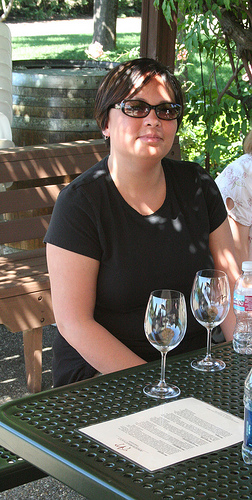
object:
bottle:
[232, 260, 252, 355]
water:
[232, 275, 252, 357]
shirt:
[42, 151, 231, 394]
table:
[0, 333, 251, 497]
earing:
[103, 136, 109, 142]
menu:
[78, 393, 244, 477]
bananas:
[91, 47, 192, 173]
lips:
[136, 133, 162, 149]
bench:
[0, 133, 180, 394]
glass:
[142, 288, 188, 401]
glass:
[189, 269, 230, 372]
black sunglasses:
[111, 98, 182, 120]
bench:
[1, 443, 49, 495]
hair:
[93, 57, 184, 148]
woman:
[46, 56, 247, 386]